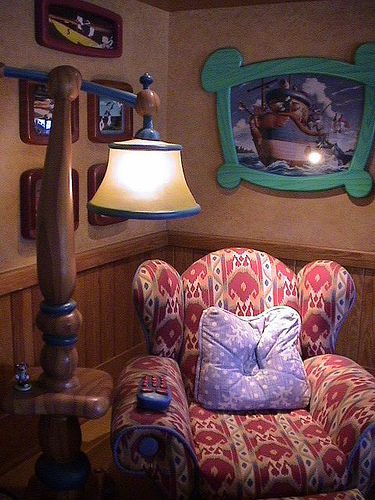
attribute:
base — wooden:
[24, 414, 100, 499]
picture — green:
[229, 72, 365, 177]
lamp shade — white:
[85, 138, 202, 218]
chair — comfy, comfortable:
[110, 242, 372, 498]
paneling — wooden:
[2, 233, 185, 364]